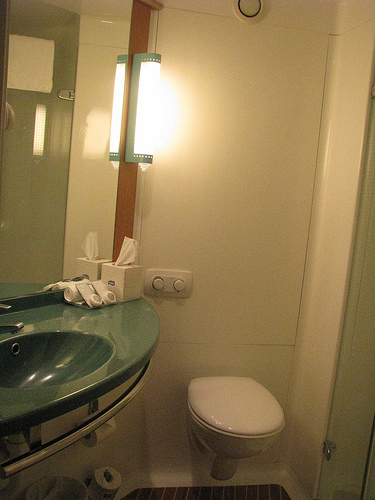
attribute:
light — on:
[127, 57, 172, 166]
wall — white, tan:
[92, 1, 291, 330]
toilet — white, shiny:
[192, 381, 281, 459]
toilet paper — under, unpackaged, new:
[91, 424, 133, 449]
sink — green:
[9, 298, 155, 420]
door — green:
[14, 12, 67, 299]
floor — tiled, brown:
[143, 481, 298, 500]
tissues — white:
[112, 246, 155, 319]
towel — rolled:
[60, 275, 118, 318]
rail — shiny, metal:
[117, 376, 180, 399]